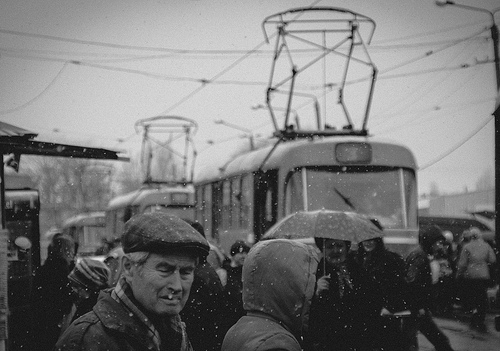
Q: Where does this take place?
A: In a city.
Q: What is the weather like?
A: It is snowing.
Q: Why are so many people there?
A: To catch a bus.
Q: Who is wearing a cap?
A: A man.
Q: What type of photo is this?
A: Black and white.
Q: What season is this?
A: Winter.